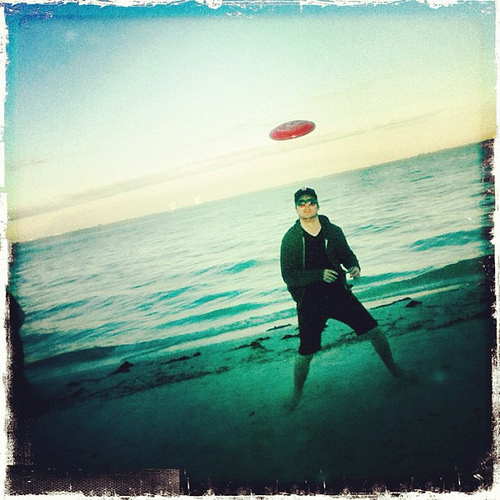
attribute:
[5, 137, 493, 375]
water — calm